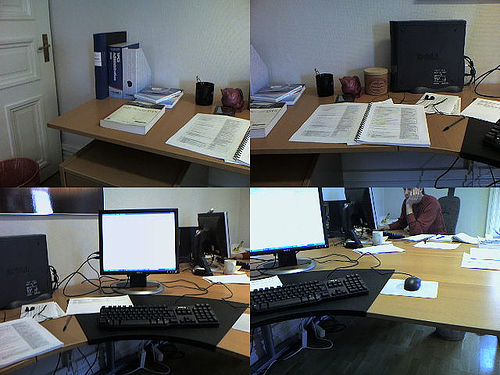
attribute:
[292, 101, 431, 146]
book — open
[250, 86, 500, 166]
table — wooden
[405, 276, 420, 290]
mouse — black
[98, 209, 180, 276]
monitor — on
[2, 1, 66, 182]
door — white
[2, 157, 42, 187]
can — trash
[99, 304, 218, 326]
keyboard — black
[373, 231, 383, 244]
cup — white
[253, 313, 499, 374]
floor — brown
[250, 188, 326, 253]
screen — white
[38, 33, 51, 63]
handle — brass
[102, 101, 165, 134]
book — cream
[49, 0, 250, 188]
wall — white